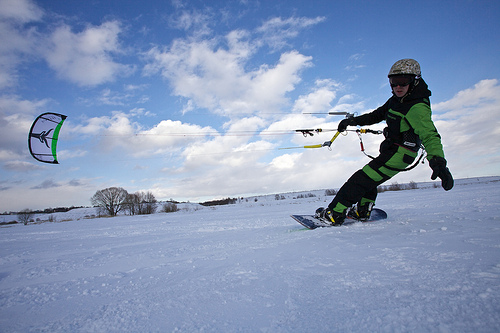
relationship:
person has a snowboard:
[317, 59, 455, 225] [290, 201, 392, 230]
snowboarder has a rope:
[317, 59, 455, 225] [357, 134, 427, 175]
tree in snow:
[92, 187, 127, 215] [3, 178, 500, 330]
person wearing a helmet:
[317, 59, 455, 225] [387, 56, 422, 77]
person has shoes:
[317, 59, 455, 225] [315, 205, 372, 226]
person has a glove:
[317, 59, 455, 225] [430, 156, 455, 192]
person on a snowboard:
[317, 59, 455, 225] [290, 201, 392, 230]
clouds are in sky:
[151, 24, 334, 113] [0, 0, 498, 216]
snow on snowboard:
[306, 214, 328, 228] [290, 201, 392, 230]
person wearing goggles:
[317, 59, 455, 225] [389, 74, 416, 87]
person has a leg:
[317, 59, 455, 225] [323, 143, 431, 216]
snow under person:
[3, 178, 500, 330] [317, 59, 455, 225]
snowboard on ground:
[290, 201, 392, 230] [7, 179, 496, 331]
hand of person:
[336, 117, 350, 132] [317, 59, 455, 225]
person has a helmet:
[317, 59, 455, 225] [387, 56, 422, 77]